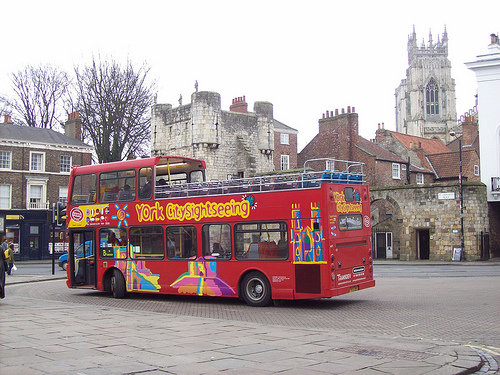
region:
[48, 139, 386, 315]
red double decker bus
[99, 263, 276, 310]
black tires on side of bus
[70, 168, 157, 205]
windows on side of double decker top level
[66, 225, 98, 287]
door on side of bus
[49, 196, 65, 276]
black traffic light on black pole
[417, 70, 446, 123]
arched window on front of stone building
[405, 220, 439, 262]
black door on front of stone building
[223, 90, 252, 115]
chimney on top of building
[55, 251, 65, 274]
front of blue car on street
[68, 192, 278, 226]
colorful sign on the red bus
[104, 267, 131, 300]
the front wheel is turning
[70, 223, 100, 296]
the access door on the bus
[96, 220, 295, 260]
the side windows on the bus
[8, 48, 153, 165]
trees by the buildings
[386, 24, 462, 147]
a gothic tower in the distance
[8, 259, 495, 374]
pavers cover the street and sidewalk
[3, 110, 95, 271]
a building in front of the bus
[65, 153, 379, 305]
a red double deck bus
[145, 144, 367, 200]
the upper deck has an open-air portion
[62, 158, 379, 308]
double decker tour bus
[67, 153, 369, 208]
second deck of tour bus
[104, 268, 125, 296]
left front tire of tour bus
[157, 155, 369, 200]
safety rail of tour bus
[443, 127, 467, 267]
tall street light on sidewalk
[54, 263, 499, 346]
cobble stone paved street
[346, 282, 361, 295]
rear license plate of tour bus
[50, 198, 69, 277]
traffic light at intersection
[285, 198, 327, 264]
brightly colored castle painted on bus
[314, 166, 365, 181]
row of blue seats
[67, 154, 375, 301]
A colorful double-decker tour bus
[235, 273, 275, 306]
A vehicle tire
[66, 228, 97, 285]
An open bus door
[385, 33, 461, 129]
A tall Gothic style tower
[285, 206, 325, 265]
A colorful image of a castle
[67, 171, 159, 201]
A trio of wide windows on a bus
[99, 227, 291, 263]
A series of side windows on a bus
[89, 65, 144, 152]
A stark tree with no leaves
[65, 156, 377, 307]
red double decker bus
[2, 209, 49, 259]
black front door of building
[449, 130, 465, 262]
tall black street light pole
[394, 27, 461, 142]
tall tower part of a building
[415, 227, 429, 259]
black door on a brick building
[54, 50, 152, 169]
tree with no leaves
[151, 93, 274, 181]
old white building with black on it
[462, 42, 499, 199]
white building on the right